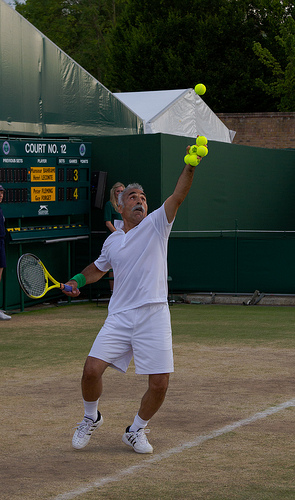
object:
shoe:
[69, 412, 102, 450]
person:
[105, 181, 125, 230]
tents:
[8, 18, 232, 154]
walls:
[24, 136, 288, 290]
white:
[75, 206, 177, 470]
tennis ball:
[194, 82, 209, 100]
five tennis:
[183, 133, 212, 170]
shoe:
[124, 422, 153, 455]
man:
[61, 139, 204, 453]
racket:
[11, 239, 109, 338]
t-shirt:
[86, 202, 181, 311]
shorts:
[82, 304, 175, 377]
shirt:
[94, 201, 176, 315]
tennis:
[175, 68, 220, 205]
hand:
[43, 269, 88, 305]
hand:
[182, 140, 206, 169]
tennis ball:
[194, 143, 209, 157]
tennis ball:
[188, 143, 197, 154]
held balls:
[179, 135, 208, 166]